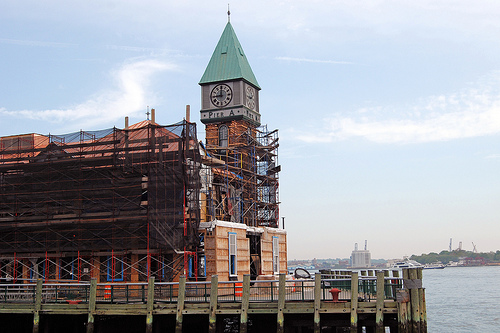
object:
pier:
[216, 253, 432, 331]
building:
[2, 0, 295, 298]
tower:
[180, 0, 278, 236]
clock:
[205, 81, 237, 111]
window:
[228, 231, 240, 279]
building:
[342, 236, 377, 269]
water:
[426, 265, 499, 332]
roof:
[187, 4, 274, 95]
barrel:
[0, 285, 401, 306]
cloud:
[295, 86, 497, 147]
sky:
[262, 0, 499, 147]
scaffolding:
[176, 101, 289, 248]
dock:
[1, 267, 429, 332]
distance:
[281, 227, 500, 269]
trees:
[439, 251, 449, 261]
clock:
[243, 83, 260, 113]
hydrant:
[322, 286, 347, 306]